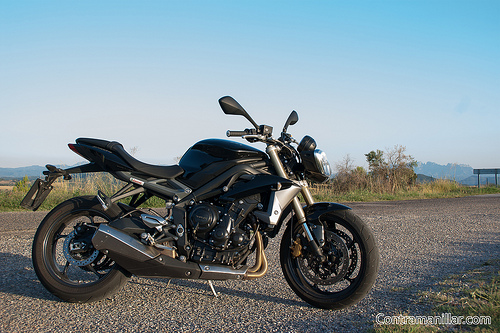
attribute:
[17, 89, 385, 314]
motorcycle — black, sitting, parked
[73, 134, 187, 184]
seat — contour, curved, cushion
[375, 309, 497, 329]
letters — white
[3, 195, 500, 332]
road — gravel, dirt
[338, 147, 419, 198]
trees — brown, green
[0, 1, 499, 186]
sky — blue, empty, clear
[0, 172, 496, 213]
grass — green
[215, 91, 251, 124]
mirrors — black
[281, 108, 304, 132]
mirrors — black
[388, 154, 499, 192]
mountains — background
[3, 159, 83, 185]
mountains — background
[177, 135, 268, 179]
tank — shiny